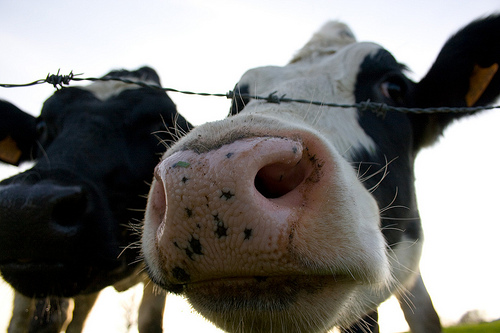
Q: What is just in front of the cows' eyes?
A: Black barbed wire.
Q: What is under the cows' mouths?
A: White whiskers.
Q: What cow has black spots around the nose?
A: Right cow.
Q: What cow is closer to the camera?
A: White and brown cow.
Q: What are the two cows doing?
A: Looking through the barbed wire fence.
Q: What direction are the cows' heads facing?
A: Down towards the camera.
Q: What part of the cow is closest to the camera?
A: The nose.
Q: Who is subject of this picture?
A: Cows.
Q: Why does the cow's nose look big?
A: It's closest to the camera.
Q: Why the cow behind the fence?
A: It's barbed.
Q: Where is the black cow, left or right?
A: Left.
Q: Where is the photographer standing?
A: Behind the fence.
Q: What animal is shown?
A: Cow.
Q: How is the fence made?
A: Barbed.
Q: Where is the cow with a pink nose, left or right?
A: Right.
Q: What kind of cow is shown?
A: Milk cow.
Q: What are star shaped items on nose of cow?
A: Black spots.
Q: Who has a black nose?
A: Cow on left.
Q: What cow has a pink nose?
A: Cow on right.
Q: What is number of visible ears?
A: Two.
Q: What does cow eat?
A: Green grass in background.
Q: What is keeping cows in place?
A: Barbed wire fence.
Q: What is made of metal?
A: The fence.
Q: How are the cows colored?
A: Black and white.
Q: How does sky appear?
A: It is clear.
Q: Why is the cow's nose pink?
A: Genetics.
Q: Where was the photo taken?
A: Outdoors at a farm.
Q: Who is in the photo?
A: No one.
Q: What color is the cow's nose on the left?
A: Black.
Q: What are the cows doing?
A: Looking at the barbed wire fence.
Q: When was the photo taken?
A: Daytime.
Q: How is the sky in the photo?
A: Sunny.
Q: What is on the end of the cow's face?
A: Whiskers.